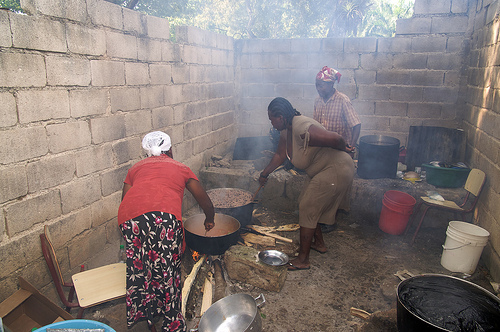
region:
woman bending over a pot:
[101, 109, 225, 328]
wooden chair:
[28, 207, 150, 322]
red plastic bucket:
[370, 176, 420, 246]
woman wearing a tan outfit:
[222, 76, 378, 281]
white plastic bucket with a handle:
[429, 196, 493, 288]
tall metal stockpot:
[348, 121, 415, 203]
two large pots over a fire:
[171, 159, 294, 294]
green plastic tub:
[406, 132, 473, 194]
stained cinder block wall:
[6, 0, 268, 291]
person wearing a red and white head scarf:
[299, 60, 366, 232]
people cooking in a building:
[6, 6, 496, 328]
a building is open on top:
[3, 5, 498, 118]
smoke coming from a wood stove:
[159, 0, 445, 277]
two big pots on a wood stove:
[179, 173, 274, 270]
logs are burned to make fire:
[180, 220, 302, 305]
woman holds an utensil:
[106, 116, 239, 329]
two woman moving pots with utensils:
[104, 96, 366, 324]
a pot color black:
[381, 262, 498, 328]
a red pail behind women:
[371, 179, 419, 242]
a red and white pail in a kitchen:
[361, 176, 496, 272]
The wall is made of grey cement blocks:
[5, 10, 471, 255]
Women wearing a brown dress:
[260, 95, 365, 245]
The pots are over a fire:
[191, 172, 286, 267]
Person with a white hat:
[115, 117, 207, 197]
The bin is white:
[420, 215, 490, 272]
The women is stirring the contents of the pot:
[202, 85, 357, 265]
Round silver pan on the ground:
[253, 242, 298, 268]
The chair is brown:
[407, 161, 485, 245]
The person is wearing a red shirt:
[113, 128, 218, 266]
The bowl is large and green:
[418, 149, 480, 188]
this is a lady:
[126, 137, 189, 279]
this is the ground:
[293, 283, 316, 308]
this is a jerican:
[448, 228, 492, 264]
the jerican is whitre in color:
[453, 242, 472, 257]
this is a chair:
[418, 193, 451, 213]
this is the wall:
[29, 149, 92, 209]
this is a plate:
[260, 248, 284, 268]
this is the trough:
[427, 162, 464, 187]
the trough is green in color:
[429, 165, 446, 180]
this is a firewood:
[181, 262, 193, 303]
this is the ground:
[301, 280, 336, 315]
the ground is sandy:
[296, 274, 342, 326]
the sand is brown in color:
[296, 279, 316, 301]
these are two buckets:
[376, 184, 492, 268]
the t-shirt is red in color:
[138, 159, 173, 208]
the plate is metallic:
[256, 247, 288, 269]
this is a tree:
[233, 0, 361, 31]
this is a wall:
[8, 160, 78, 198]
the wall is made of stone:
[5, 158, 90, 203]